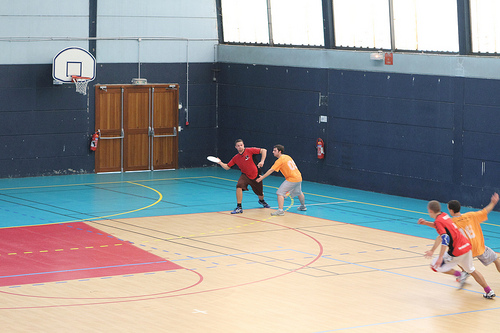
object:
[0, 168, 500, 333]
ground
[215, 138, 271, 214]
man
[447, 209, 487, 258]
shirt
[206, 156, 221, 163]
frisbee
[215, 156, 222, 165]
hand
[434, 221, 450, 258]
arm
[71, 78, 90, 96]
net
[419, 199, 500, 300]
boys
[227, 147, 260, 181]
jersey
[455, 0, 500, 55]
windows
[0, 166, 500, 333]
basketball court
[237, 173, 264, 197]
brown shorts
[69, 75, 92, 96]
basketball hoop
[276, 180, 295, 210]
leg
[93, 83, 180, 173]
door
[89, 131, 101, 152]
fire extinguisher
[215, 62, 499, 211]
wall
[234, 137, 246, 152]
head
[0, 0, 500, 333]
building